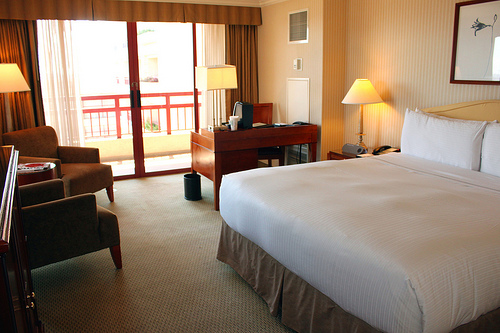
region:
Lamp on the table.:
[340, 74, 384, 154]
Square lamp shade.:
[192, 63, 239, 92]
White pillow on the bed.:
[397, 105, 484, 174]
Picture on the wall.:
[446, 0, 498, 85]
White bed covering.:
[217, 150, 497, 330]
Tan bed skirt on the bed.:
[210, 222, 367, 330]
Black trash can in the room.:
[181, 170, 203, 200]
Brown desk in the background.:
[186, 117, 318, 208]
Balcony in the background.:
[43, 93, 248, 171]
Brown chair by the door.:
[3, 125, 124, 205]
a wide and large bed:
[217, 107, 499, 331]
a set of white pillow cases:
[397, 104, 499, 178]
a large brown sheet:
[214, 217, 499, 332]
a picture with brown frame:
[449, 24, 498, 88]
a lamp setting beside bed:
[326, 76, 384, 160]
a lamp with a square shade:
[196, 63, 239, 133]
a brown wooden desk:
[189, 119, 324, 211]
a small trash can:
[182, 169, 204, 201]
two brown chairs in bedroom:
[0, 123, 125, 318]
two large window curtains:
[0, 0, 265, 182]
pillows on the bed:
[398, 103, 499, 173]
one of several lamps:
[201, 65, 238, 121]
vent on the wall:
[278, 10, 312, 47]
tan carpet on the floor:
[126, 204, 215, 326]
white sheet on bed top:
[273, 176, 437, 258]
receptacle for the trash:
[178, 169, 205, 204]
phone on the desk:
[368, 144, 398, 156]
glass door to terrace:
[132, 24, 188, 173]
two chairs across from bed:
[3, 115, 125, 286]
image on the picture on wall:
[467, 13, 499, 83]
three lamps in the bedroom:
[3, 60, 383, 159]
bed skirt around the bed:
[213, 223, 386, 331]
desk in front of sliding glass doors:
[188, 119, 318, 204]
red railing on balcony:
[81, 89, 197, 141]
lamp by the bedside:
[338, 77, 385, 151]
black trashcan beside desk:
[183, 169, 199, 199]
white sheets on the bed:
[223, 146, 496, 326]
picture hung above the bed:
[440, 4, 498, 87]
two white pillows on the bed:
[393, 109, 498, 172]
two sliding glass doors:
[33, 22, 233, 174]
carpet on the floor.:
[161, 261, 181, 287]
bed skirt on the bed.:
[287, 295, 316, 327]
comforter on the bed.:
[367, 181, 407, 243]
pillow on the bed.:
[415, 121, 460, 148]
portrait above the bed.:
[464, 18, 499, 71]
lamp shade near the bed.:
[345, 84, 373, 100]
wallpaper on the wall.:
[386, 26, 411, 56]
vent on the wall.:
[293, 16, 307, 38]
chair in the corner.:
[47, 151, 86, 170]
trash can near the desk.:
[180, 173, 202, 204]